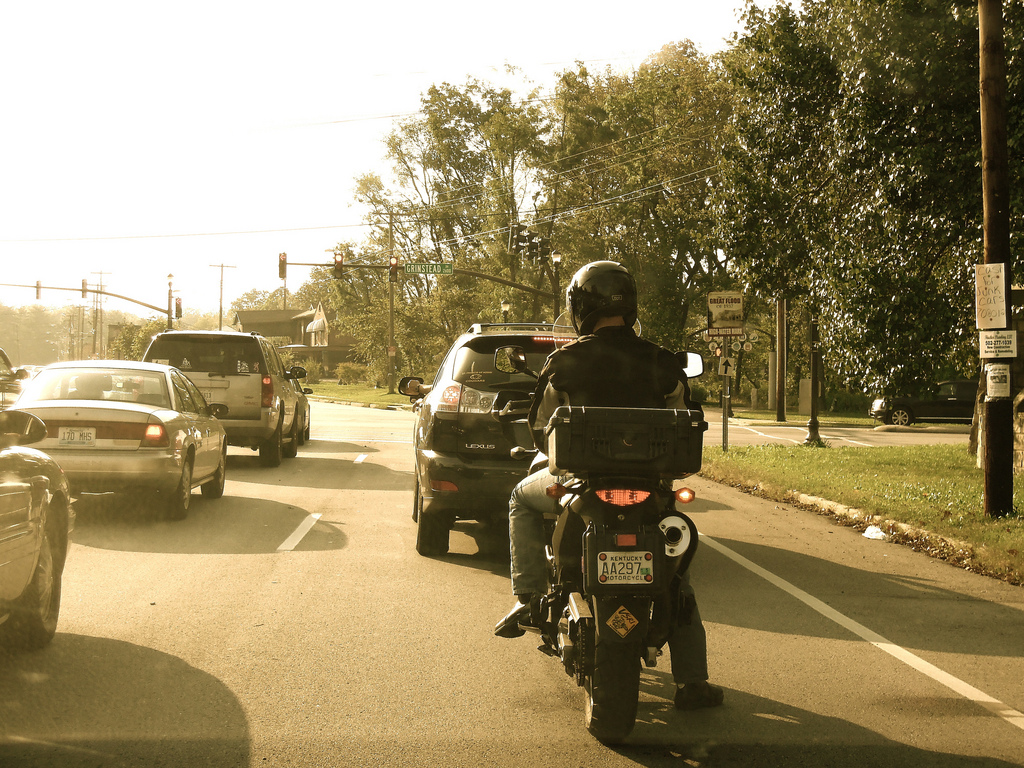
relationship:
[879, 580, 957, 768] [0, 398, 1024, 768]
line on road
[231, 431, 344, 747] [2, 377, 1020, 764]
dash marks on road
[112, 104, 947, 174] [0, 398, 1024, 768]
traffic signals above road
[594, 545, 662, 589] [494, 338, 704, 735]
license plate on motorcycle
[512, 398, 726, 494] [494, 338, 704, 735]
case on motorcycle